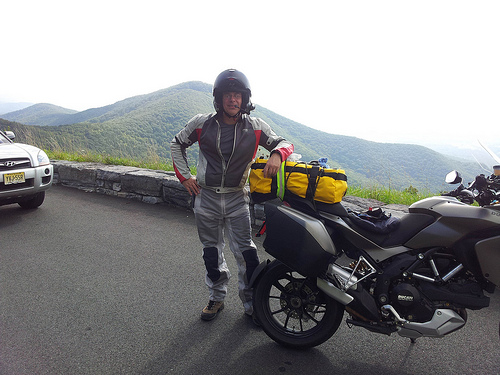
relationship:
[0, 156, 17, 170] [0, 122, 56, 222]
logo on car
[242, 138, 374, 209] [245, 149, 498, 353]
bag on motorcycle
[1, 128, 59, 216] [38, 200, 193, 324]
car on road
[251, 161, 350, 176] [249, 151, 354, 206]
strap on bag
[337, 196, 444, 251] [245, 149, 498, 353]
seat on motorcycle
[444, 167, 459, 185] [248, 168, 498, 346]
mirror on motorcycle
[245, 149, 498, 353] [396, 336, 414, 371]
motorcycle has kickstand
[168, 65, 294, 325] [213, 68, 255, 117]
man wearing helmet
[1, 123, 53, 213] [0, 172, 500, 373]
suv on road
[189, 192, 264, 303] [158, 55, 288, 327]
silver pants on rider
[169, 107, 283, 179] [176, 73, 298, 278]
jacket on man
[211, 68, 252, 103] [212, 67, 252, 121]
helmet on head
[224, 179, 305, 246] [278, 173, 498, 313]
plate on vehicle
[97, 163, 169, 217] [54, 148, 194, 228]
brick on border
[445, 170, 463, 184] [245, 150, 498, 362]
mirror on bike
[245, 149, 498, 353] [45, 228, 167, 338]
motorcycle on road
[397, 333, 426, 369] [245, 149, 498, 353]
kickstand on motorcycle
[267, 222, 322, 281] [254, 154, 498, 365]
tank on motorcycle